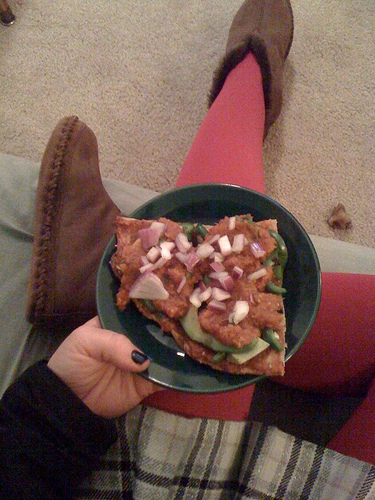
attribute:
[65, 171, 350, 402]
plate — green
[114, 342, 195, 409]
finger nail — painted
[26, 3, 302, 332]
shoes — brown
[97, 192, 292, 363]
pizza — sliced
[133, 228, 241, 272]
onions — chopped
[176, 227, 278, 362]
peppers — chopped, green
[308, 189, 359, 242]
nose — fake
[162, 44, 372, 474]
leggings — red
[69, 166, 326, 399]
plate — green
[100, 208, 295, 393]
pizza — sliced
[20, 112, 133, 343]
slipper — brown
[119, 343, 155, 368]
polish — black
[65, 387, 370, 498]
couch material — patterned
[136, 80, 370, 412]
tights — red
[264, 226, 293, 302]
peppers — green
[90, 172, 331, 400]
plate — green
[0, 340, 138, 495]
sleeve — black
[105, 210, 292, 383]
pizza — sliced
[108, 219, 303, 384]
pizza — sliced